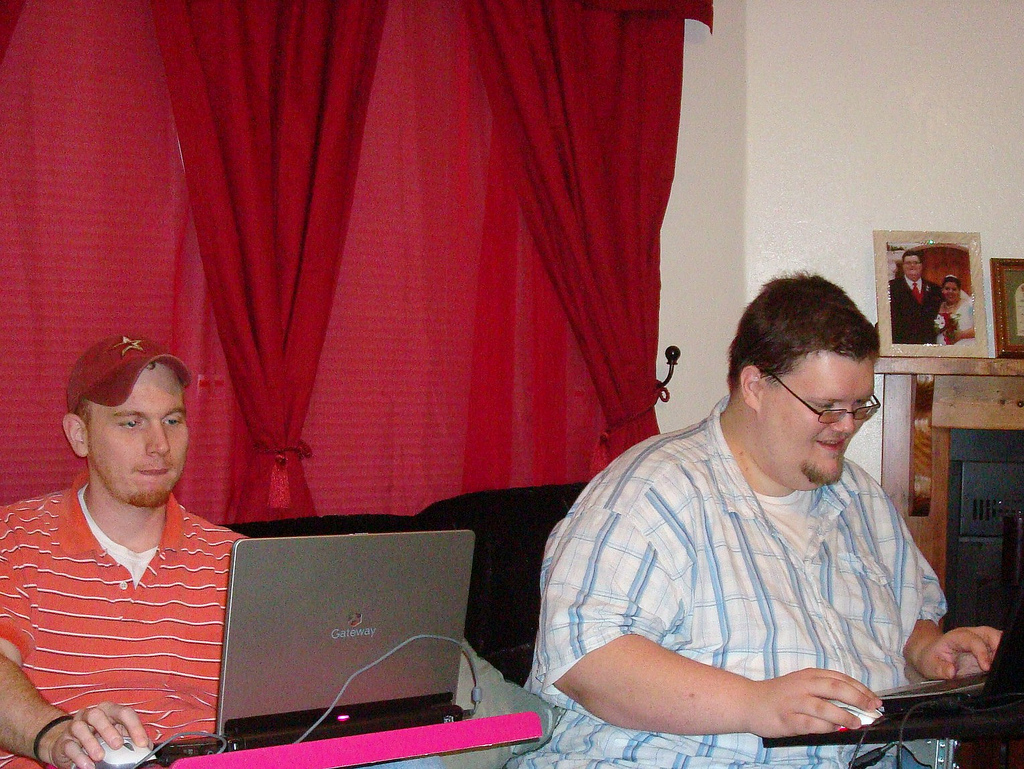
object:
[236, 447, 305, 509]
ties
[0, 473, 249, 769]
shirt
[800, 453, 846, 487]
beard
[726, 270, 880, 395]
hair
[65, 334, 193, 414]
hat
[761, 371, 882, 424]
eyeglasses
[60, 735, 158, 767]
mouse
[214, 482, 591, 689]
black couch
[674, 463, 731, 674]
blue stripe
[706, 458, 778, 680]
blue stripe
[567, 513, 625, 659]
blue stripe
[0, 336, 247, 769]
man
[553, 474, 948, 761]
shirt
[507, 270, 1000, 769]
man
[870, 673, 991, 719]
keyboard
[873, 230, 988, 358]
frame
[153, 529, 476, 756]
computer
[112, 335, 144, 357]
logo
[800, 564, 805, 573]
button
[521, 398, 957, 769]
stripes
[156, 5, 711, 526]
curtains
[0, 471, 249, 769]
polo